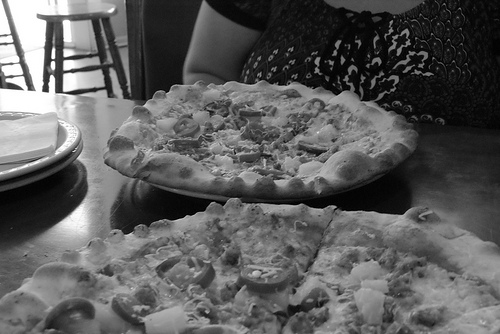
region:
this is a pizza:
[95, 196, 415, 326]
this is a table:
[428, 139, 496, 211]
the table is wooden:
[49, 185, 103, 226]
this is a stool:
[40, 4, 135, 78]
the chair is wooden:
[51, 5, 117, 44]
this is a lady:
[249, 2, 438, 87]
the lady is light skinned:
[188, 20, 234, 67]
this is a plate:
[10, 144, 45, 169]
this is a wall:
[141, 17, 167, 49]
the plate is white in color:
[61, 128, 91, 148]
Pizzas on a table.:
[2, 79, 499, 332]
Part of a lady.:
[179, 0, 498, 130]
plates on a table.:
[0, 110, 85, 194]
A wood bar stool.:
[34, 0, 131, 102]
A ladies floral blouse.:
[203, 1, 498, 130]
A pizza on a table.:
[100, 75, 420, 206]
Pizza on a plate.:
[99, 78, 422, 206]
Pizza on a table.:
[0, 86, 498, 332]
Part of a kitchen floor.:
[0, 43, 134, 100]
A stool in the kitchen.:
[36, 1, 132, 97]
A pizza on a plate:
[107, 84, 414, 194]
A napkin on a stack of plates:
[0, 112, 57, 158]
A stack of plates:
[0, 100, 83, 197]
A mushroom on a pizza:
[241, 259, 291, 293]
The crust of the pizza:
[145, 148, 368, 198]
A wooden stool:
[31, 0, 134, 100]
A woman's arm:
[182, 12, 250, 87]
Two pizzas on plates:
[6, 77, 495, 331]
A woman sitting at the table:
[187, 6, 499, 125]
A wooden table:
[2, 90, 489, 330]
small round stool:
[34, 4, 129, 89]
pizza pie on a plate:
[134, 75, 408, 197]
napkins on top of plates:
[14, 103, 86, 180]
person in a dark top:
[217, 0, 484, 97]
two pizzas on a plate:
[121, 78, 449, 330]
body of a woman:
[196, 3, 483, 91]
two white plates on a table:
[17, 103, 96, 187]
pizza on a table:
[101, 76, 406, 208]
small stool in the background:
[29, 2, 149, 80]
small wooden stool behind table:
[39, 3, 151, 90]